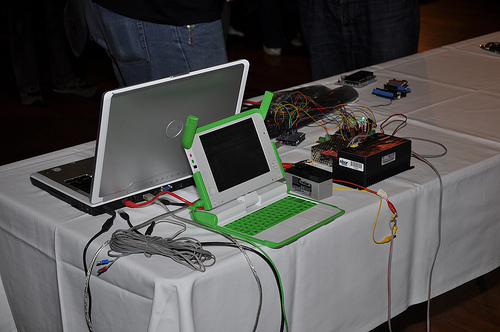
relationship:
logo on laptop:
[162, 115, 187, 142] [72, 75, 262, 202]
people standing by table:
[79, 0, 230, 88] [2, 31, 498, 329]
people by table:
[79, 0, 230, 88] [2, 31, 498, 329]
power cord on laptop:
[72, 209, 119, 279] [35, 60, 224, 215]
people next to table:
[95, 2, 435, 61] [2, 31, 498, 329]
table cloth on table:
[0, 29, 500, 330] [2, 31, 498, 329]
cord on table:
[98, 214, 213, 271] [2, 31, 498, 329]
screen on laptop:
[198, 117, 271, 192] [42, 56, 382, 273]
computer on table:
[28, 59, 250, 217] [2, 31, 498, 329]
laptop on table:
[182, 87, 345, 247] [2, 31, 498, 329]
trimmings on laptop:
[31, 57, 251, 207] [22, 60, 250, 200]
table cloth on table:
[102, 240, 252, 310] [350, 52, 499, 229]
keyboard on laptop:
[223, 185, 313, 244] [153, 105, 367, 276]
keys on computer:
[67, 173, 91, 193] [28, 57, 252, 219]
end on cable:
[95, 266, 106, 275] [96, 225, 214, 277]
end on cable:
[93, 257, 109, 264] [96, 225, 214, 277]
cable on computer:
[121, 187, 200, 209] [28, 57, 252, 219]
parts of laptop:
[250, 84, 411, 192] [34, 39, 285, 240]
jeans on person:
[85, 2, 190, 84] [81, 10, 243, 95]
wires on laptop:
[227, 228, 470, 329] [182, 87, 345, 247]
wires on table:
[106, 215, 214, 273] [2, 31, 498, 329]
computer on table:
[28, 59, 250, 217] [9, 149, 236, 319]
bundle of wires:
[77, 199, 226, 276] [69, 187, 351, 329]